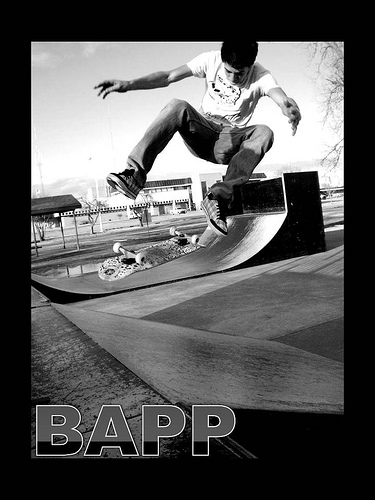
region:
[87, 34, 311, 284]
A man and a skateboard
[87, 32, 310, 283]
man performing a skateboard trick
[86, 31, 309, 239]
man in the air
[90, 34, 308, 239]
man wearing jeans and a shirt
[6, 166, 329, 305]
a low skateboard ramp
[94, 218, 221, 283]
a skateboard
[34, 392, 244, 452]
letters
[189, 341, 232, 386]
a ramp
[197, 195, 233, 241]
man is wearing shoes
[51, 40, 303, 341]
a guy is flipping his skateboard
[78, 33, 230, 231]
a guy is flipping his skateboard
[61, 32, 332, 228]
man is playing skateboard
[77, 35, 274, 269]
the boy is playing his skateboard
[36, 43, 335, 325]
A skateboarder doing a kick flip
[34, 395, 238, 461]
a text decoration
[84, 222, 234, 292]
a painted skateboard deck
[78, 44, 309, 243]
a young man jumping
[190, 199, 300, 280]
a skateboard ramp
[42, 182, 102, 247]
a pavilion in a park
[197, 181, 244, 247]
a checkered shoe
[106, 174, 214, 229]
a large public building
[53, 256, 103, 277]
a puddle of muddy water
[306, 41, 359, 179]
a leafless tree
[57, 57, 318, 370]
The picture is in black and white.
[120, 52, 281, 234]
The boy is on a skateboard ramp.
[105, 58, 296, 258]
The boy is in the air.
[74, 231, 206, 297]
The skateboard is in the air.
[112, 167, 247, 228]
The boy is wearing stripe sneakers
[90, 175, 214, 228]
A building is in the background.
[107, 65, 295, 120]
The boy has his arms spead out.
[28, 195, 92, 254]
A canopy sit near the skateboard ramp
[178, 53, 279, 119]
The boy is wearing a white t-shirt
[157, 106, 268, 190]
The boy is wearing jeans.